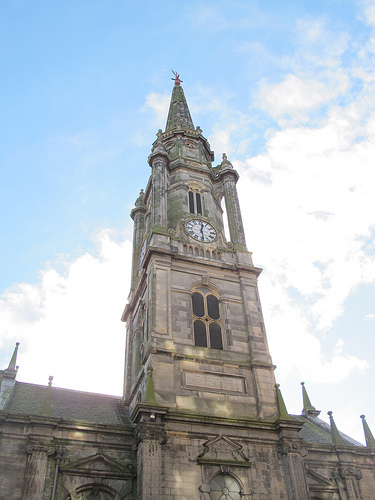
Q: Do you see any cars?
A: No, there are no cars.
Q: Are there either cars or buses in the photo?
A: No, there are no cars or buses.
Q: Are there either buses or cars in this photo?
A: No, there are no cars or buses.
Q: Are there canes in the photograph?
A: No, there are no canes.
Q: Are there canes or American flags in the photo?
A: No, there are no canes or American flags.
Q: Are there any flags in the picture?
A: No, there are no flags.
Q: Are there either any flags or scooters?
A: No, there are no flags or scooters.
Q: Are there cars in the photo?
A: No, there are no cars.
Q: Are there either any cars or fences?
A: No, there are no cars or fences.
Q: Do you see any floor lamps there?
A: No, there are no floor lamps.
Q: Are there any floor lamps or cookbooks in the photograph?
A: No, there are no floor lamps or cookbooks.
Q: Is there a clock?
A: Yes, there is a clock.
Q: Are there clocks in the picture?
A: Yes, there is a clock.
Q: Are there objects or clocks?
A: Yes, there is a clock.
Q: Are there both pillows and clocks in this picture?
A: No, there is a clock but no pillows.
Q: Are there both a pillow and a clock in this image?
A: No, there is a clock but no pillows.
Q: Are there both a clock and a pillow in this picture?
A: No, there is a clock but no pillows.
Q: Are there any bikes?
A: No, there are no bikes.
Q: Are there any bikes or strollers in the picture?
A: No, there are no bikes or strollers.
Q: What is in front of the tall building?
A: The clock is in front of the tower.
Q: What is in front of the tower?
A: The clock is in front of the tower.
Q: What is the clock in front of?
A: The clock is in front of the tower.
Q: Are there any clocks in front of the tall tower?
A: Yes, there is a clock in front of the tower.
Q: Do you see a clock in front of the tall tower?
A: Yes, there is a clock in front of the tower.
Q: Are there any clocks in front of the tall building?
A: Yes, there is a clock in front of the tower.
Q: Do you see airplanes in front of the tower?
A: No, there is a clock in front of the tower.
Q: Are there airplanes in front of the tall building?
A: No, there is a clock in front of the tower.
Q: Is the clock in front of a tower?
A: Yes, the clock is in front of a tower.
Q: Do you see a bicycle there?
A: No, there are no bicycles.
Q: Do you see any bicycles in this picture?
A: No, there are no bicycles.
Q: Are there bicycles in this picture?
A: No, there are no bicycles.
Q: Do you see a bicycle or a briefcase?
A: No, there are no bicycles or briefcases.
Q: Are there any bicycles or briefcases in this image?
A: No, there are no bicycles or briefcases.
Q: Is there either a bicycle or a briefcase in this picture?
A: No, there are no bicycles or briefcases.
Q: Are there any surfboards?
A: No, there are no surfboards.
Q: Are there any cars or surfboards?
A: No, there are no surfboards or cars.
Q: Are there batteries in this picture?
A: No, there are no batteries.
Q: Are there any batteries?
A: No, there are no batteries.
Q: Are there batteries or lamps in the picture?
A: No, there are no batteries or lamps.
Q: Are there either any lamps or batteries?
A: No, there are no batteries or lamps.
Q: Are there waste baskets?
A: No, there are no waste baskets.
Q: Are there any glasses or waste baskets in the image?
A: No, there are no waste baskets or glasses.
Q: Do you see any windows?
A: Yes, there is a window.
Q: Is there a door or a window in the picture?
A: Yes, there is a window.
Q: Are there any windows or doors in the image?
A: Yes, there is a window.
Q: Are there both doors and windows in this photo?
A: No, there is a window but no doors.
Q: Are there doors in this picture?
A: No, there are no doors.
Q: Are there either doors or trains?
A: No, there are no doors or trains.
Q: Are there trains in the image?
A: No, there are no trains.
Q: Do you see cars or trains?
A: No, there are no trains or cars.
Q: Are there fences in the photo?
A: No, there are no fences.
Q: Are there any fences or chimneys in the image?
A: No, there are no fences or chimneys.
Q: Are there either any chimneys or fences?
A: No, there are no fences or chimneys.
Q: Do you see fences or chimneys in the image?
A: No, there are no fences or chimneys.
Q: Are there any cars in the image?
A: No, there are no cars.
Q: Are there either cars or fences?
A: No, there are no cars or fences.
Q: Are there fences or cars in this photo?
A: No, there are no cars or fences.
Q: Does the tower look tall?
A: Yes, the tower is tall.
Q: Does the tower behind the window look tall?
A: Yes, the tower is tall.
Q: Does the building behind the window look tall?
A: Yes, the tower is tall.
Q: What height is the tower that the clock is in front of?
A: The tower is tall.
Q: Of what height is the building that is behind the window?
A: The tower is tall.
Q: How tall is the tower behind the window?
A: The tower is tall.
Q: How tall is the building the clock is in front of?
A: The tower is tall.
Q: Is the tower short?
A: No, the tower is tall.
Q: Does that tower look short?
A: No, the tower is tall.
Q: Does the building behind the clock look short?
A: No, the tower is tall.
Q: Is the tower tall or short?
A: The tower is tall.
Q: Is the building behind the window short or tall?
A: The tower is tall.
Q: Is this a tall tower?
A: Yes, this is a tall tower.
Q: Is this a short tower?
A: No, this is a tall tower.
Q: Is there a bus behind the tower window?
A: No, there is a tower behind the window.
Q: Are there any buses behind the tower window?
A: No, there is a tower behind the window.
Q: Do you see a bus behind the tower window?
A: No, there is a tower behind the window.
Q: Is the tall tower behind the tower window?
A: Yes, the tower is behind the window.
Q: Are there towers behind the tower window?
A: Yes, there is a tower behind the window.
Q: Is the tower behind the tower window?
A: Yes, the tower is behind the window.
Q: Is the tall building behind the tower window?
A: Yes, the tower is behind the window.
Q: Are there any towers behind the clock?
A: Yes, there is a tower behind the clock.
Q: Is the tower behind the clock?
A: Yes, the tower is behind the clock.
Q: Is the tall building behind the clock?
A: Yes, the tower is behind the clock.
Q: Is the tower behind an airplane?
A: No, the tower is behind the clock.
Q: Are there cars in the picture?
A: No, there are no cars.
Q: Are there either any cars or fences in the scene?
A: No, there are no cars or fences.